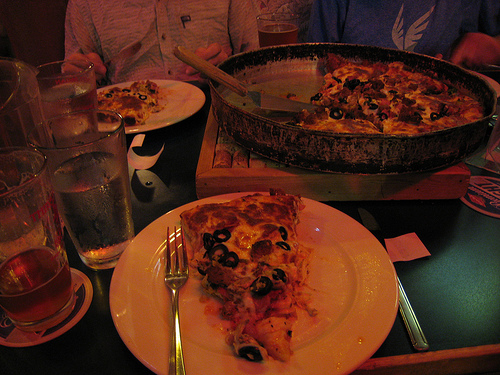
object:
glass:
[26, 108, 135, 271]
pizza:
[285, 55, 485, 134]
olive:
[249, 275, 273, 299]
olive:
[217, 251, 239, 269]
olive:
[238, 346, 263, 363]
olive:
[196, 266, 206, 276]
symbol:
[391, 2, 435, 52]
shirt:
[299, 0, 481, 61]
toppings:
[197, 226, 291, 300]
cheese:
[178, 187, 318, 362]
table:
[0, 66, 500, 375]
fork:
[164, 226, 190, 375]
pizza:
[95, 79, 168, 126]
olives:
[278, 226, 288, 241]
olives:
[275, 241, 290, 251]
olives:
[272, 268, 287, 283]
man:
[61, 1, 262, 82]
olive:
[213, 227, 232, 243]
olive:
[329, 106, 344, 119]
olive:
[430, 112, 440, 122]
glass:
[0, 147, 78, 333]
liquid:
[51, 151, 135, 263]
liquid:
[0, 247, 74, 322]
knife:
[350, 208, 429, 351]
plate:
[109, 191, 399, 375]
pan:
[208, 43, 498, 176]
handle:
[173, 45, 329, 114]